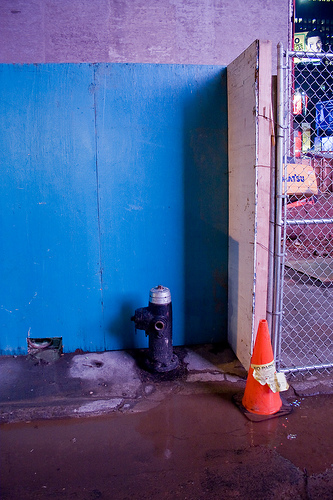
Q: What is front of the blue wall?
A: A fire hydrant.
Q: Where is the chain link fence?
A: On the right of the photo.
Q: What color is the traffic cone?
A: Orange.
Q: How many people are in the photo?
A: None.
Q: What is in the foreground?
A: A puddle.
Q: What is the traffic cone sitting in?
A: Water.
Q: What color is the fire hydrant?
A: Black and silver.